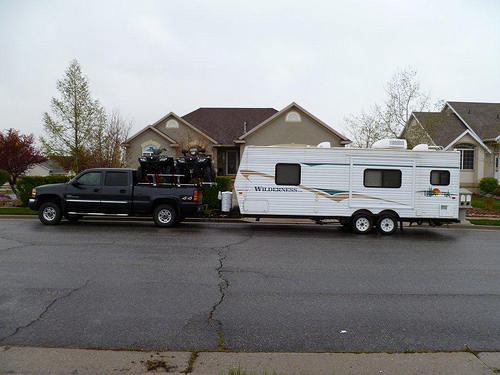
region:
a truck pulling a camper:
[55, 105, 424, 252]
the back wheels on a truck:
[145, 175, 198, 248]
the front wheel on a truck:
[27, 202, 78, 246]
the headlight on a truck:
[18, 173, 51, 223]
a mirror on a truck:
[57, 161, 82, 197]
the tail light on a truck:
[176, 174, 212, 221]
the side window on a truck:
[44, 140, 159, 203]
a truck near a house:
[31, 133, 213, 236]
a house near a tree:
[81, 60, 288, 245]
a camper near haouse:
[25, 55, 388, 235]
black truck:
[41, 149, 216, 229]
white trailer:
[244, 152, 461, 219]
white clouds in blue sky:
[45, 18, 89, 38]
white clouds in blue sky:
[297, 32, 324, 66]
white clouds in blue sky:
[218, 39, 259, 77]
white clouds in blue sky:
[424, 13, 456, 37]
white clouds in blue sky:
[317, 35, 394, 86]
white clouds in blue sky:
[178, 16, 209, 50]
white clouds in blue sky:
[155, 23, 220, 74]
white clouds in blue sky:
[102, 32, 166, 66]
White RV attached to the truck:
[217, 135, 467, 240]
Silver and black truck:
[23, 167, 208, 228]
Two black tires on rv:
[344, 210, 412, 241]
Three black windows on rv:
[271, 157, 454, 197]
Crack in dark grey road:
[187, 192, 269, 366]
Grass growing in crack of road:
[3, 335, 499, 374]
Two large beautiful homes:
[119, 85, 497, 214]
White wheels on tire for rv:
[355, 211, 400, 236]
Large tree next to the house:
[33, 59, 128, 188]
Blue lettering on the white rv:
[248, 181, 301, 196]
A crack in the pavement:
[204, 238, 240, 321]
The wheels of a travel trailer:
[343, 208, 404, 238]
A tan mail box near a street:
[456, 185, 475, 230]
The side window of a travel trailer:
[359, 162, 406, 198]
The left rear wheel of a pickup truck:
[146, 196, 181, 231]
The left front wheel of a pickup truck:
[33, 194, 67, 231]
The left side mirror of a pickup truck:
[66, 177, 80, 190]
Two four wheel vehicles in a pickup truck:
[133, 141, 223, 194]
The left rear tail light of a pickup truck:
[188, 187, 203, 209]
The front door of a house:
[220, 146, 240, 179]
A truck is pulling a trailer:
[27, 143, 467, 242]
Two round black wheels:
[347, 208, 402, 239]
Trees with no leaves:
[346, 63, 446, 150]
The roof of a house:
[182, 104, 280, 145]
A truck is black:
[26, 162, 206, 235]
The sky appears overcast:
[2, 3, 497, 152]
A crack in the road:
[208, 221, 255, 349]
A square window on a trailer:
[272, 161, 304, 189]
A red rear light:
[188, 186, 202, 206]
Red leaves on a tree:
[1, 127, 48, 179]